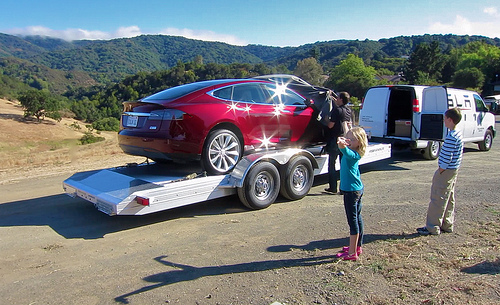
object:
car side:
[190, 84, 330, 171]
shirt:
[438, 130, 465, 171]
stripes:
[443, 141, 456, 146]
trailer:
[63, 143, 392, 218]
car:
[118, 76, 348, 174]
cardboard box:
[395, 119, 413, 136]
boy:
[417, 108, 464, 235]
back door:
[358, 86, 421, 138]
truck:
[357, 85, 495, 160]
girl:
[334, 128, 369, 263]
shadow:
[114, 254, 355, 304]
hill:
[1, 32, 28, 60]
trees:
[451, 68, 482, 89]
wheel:
[203, 128, 243, 175]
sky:
[1, 0, 498, 37]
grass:
[484, 291, 498, 304]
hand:
[437, 169, 442, 175]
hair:
[343, 126, 368, 156]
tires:
[238, 163, 281, 210]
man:
[323, 92, 353, 195]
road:
[0, 213, 499, 302]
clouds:
[20, 11, 50, 39]